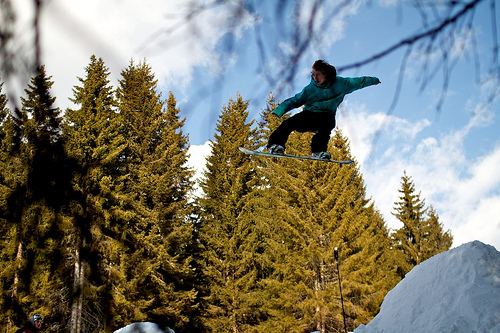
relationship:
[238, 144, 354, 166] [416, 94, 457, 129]
board moving through air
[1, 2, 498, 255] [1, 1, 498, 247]
clouds in sky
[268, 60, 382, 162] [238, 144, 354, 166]
man with board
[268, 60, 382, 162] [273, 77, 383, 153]
man wears snowsuit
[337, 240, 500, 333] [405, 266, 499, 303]
ground full of snow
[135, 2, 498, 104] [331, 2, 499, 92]
tree has branches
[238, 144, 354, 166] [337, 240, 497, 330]
board over ground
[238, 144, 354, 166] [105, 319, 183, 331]
board over ground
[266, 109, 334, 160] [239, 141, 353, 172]
knees over board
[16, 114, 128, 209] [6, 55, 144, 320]
shadow across tree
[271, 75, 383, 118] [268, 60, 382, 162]
coat on man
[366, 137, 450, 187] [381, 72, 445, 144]
clouds in sky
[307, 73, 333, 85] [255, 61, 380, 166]
goggles on man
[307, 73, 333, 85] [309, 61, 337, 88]
goggles on head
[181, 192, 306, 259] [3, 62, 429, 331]
leaves of trees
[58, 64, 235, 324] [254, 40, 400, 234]
tree above person